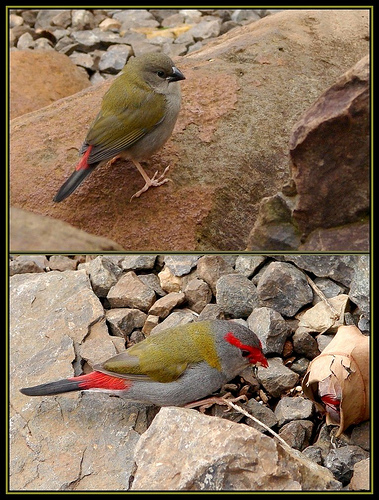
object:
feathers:
[100, 326, 215, 381]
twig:
[304, 275, 340, 319]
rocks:
[9, 254, 47, 276]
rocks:
[256, 259, 314, 318]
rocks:
[182, 279, 213, 316]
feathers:
[20, 369, 123, 395]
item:
[321, 396, 340, 406]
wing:
[86, 92, 168, 164]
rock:
[156, 254, 194, 292]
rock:
[271, 394, 313, 427]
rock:
[324, 440, 369, 485]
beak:
[166, 66, 186, 83]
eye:
[242, 350, 251, 357]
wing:
[94, 342, 190, 381]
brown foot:
[130, 165, 174, 209]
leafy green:
[92, 83, 155, 147]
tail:
[18, 371, 128, 396]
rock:
[105, 307, 148, 338]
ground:
[9, 8, 271, 85]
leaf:
[306, 354, 331, 384]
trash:
[300, 324, 370, 437]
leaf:
[317, 376, 341, 398]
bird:
[51, 50, 186, 202]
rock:
[96, 42, 135, 76]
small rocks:
[243, 398, 276, 434]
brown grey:
[213, 272, 259, 317]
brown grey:
[160, 254, 202, 279]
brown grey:
[131, 405, 226, 492]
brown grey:
[149, 292, 182, 319]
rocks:
[142, 314, 159, 337]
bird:
[18, 320, 269, 414]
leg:
[128, 144, 145, 179]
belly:
[148, 380, 196, 401]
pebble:
[105, 271, 153, 308]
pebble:
[215, 273, 259, 317]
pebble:
[246, 307, 289, 356]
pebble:
[257, 357, 299, 398]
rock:
[288, 55, 371, 233]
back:
[107, 322, 215, 364]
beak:
[249, 351, 269, 368]